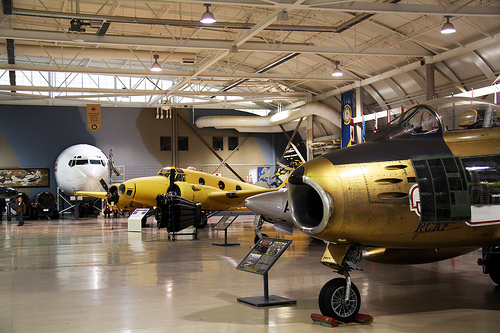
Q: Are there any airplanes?
A: Yes, there are airplanes.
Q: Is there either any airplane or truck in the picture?
A: Yes, there are airplanes.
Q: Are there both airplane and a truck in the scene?
A: No, there are airplanes but no trucks.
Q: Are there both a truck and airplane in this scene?
A: No, there are airplanes but no trucks.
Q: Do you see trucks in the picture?
A: No, there are no trucks.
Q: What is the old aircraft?
A: The aircraft is airplanes.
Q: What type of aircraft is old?
A: The aircraft is airplanes.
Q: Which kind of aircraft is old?
A: The aircraft is airplanes.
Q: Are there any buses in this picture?
A: No, there are no buses.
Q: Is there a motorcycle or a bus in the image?
A: No, there are no buses or motorcycles.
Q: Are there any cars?
A: No, there are no cars.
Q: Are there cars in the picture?
A: No, there are no cars.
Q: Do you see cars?
A: No, there are no cars.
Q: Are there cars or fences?
A: No, there are no cars or fences.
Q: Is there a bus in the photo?
A: No, there are no buses.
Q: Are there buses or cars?
A: No, there are no buses or cars.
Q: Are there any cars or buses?
A: No, there are no buses or cars.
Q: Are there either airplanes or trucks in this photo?
A: Yes, there is an airplane.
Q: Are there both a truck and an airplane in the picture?
A: No, there is an airplane but no trucks.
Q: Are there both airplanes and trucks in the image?
A: No, there is an airplane but no trucks.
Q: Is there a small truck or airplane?
A: Yes, there is a small airplane.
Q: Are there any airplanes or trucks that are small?
A: Yes, the airplane is small.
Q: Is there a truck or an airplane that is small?
A: Yes, the airplane is small.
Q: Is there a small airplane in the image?
A: Yes, there is a small airplane.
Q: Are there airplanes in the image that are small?
A: Yes, there is an airplane that is small.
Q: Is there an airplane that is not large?
A: Yes, there is a small airplane.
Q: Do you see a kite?
A: No, there are no kites.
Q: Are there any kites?
A: No, there are no kites.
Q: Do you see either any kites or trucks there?
A: No, there are no kites or trucks.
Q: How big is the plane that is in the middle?
A: The airplane is small.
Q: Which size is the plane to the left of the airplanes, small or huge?
A: The plane is small.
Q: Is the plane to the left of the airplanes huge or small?
A: The plane is small.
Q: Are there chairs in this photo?
A: No, there are no chairs.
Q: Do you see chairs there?
A: No, there are no chairs.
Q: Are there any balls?
A: No, there are no balls.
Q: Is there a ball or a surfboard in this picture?
A: No, there are no balls or surfboards.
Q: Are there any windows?
A: Yes, there are windows.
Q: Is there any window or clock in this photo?
A: Yes, there are windows.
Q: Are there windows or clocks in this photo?
A: Yes, there are windows.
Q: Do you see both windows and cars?
A: No, there are windows but no cars.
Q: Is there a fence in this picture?
A: No, there are no fences.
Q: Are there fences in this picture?
A: No, there are no fences.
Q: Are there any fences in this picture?
A: No, there are no fences.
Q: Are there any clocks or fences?
A: No, there are no fences or clocks.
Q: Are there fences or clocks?
A: No, there are no fences or clocks.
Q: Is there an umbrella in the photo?
A: No, there are no umbrellas.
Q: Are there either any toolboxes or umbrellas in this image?
A: No, there are no umbrellas or toolboxes.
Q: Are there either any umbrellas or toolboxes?
A: No, there are no umbrellas or toolboxes.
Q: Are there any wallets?
A: No, there are no wallets.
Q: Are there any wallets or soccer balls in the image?
A: No, there are no wallets or soccer balls.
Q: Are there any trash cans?
A: No, there are no trash cans.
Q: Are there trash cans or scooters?
A: No, there are no trash cans or scooters.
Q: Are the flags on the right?
A: Yes, the flags are on the right of the image.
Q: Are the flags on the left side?
A: No, the flags are on the right of the image.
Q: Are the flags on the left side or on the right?
A: The flags are on the right of the image.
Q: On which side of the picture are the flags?
A: The flags are on the right of the image.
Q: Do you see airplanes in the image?
A: Yes, there is an airplane.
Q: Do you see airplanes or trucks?
A: Yes, there is an airplane.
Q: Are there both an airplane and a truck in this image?
A: No, there is an airplane but no trucks.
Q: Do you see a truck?
A: No, there are no trucks.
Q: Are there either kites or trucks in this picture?
A: No, there are no trucks or kites.